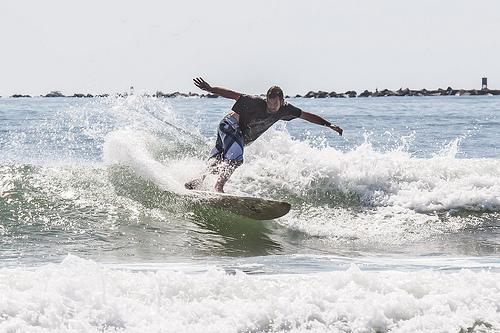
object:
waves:
[84, 92, 498, 214]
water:
[1, 96, 500, 333]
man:
[184, 77, 343, 192]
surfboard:
[186, 191, 291, 221]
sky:
[0, 0, 498, 96]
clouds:
[1, 0, 487, 76]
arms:
[192, 77, 342, 135]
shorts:
[209, 115, 244, 162]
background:
[0, 1, 499, 159]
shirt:
[231, 94, 302, 146]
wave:
[103, 94, 375, 204]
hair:
[266, 86, 283, 98]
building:
[482, 77, 488, 89]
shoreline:
[0, 77, 499, 97]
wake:
[151, 143, 194, 182]